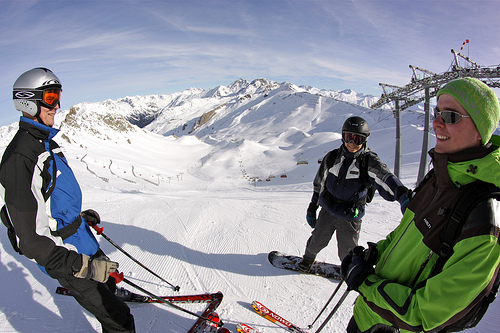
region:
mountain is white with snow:
[60, 111, 400, 322]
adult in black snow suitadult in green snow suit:
[362, 63, 497, 331]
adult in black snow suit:
[292, 102, 384, 274]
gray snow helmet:
[6, 59, 68, 130]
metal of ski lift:
[372, 64, 495, 136]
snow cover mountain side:
[195, 56, 335, 130]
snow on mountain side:
[75, 84, 190, 159]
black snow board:
[268, 238, 369, 293]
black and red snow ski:
[60, 270, 222, 320]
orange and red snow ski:
[237, 279, 328, 331]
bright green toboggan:
[434, 72, 499, 144]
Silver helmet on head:
[18, 52, 90, 127]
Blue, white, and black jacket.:
[14, 140, 152, 329]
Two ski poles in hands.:
[91, 209, 186, 329]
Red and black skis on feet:
[157, 280, 189, 319]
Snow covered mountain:
[126, 152, 225, 257]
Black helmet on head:
[329, 115, 385, 161]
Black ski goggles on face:
[328, 122, 393, 174]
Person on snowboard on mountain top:
[266, 225, 371, 326]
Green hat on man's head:
[428, 66, 487, 166]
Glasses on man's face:
[429, 71, 465, 158]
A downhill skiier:
[3, 66, 221, 330]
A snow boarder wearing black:
[267, 116, 409, 289]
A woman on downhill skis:
[236, 75, 497, 331]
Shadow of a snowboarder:
[90, 215, 307, 276]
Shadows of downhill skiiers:
[0, 226, 235, 331]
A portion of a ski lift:
[374, 39, 495, 189]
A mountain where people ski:
[83, 76, 313, 185]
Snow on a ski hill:
[125, 138, 225, 193]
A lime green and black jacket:
[337, 147, 498, 327]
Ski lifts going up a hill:
[231, 141, 311, 184]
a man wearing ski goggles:
[4, 65, 134, 331]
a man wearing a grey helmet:
[5, 63, 131, 251]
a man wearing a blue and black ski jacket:
[4, 61, 161, 313]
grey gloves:
[55, 207, 147, 309]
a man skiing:
[8, 65, 221, 332]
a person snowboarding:
[262, 81, 434, 308]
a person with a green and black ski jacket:
[361, 45, 493, 332]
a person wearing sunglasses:
[407, 31, 497, 206]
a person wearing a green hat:
[395, 59, 489, 171]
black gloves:
[321, 222, 413, 331]